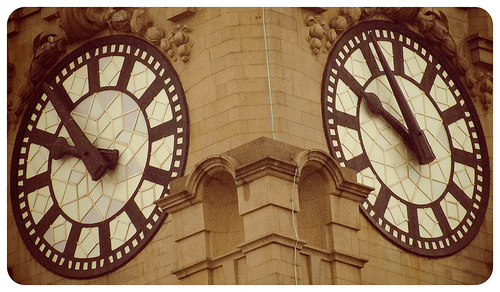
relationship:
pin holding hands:
[80, 147, 93, 157] [39, 91, 133, 177]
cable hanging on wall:
[260, 8, 277, 140] [8, 7, 493, 284]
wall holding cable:
[8, 7, 493, 284] [260, 8, 277, 140]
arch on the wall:
[181, 151, 243, 201] [162, 11, 269, 285]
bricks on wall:
[172, 7, 332, 155] [191, 37, 337, 247]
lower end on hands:
[85, 163, 107, 177] [37, 81, 115, 183]